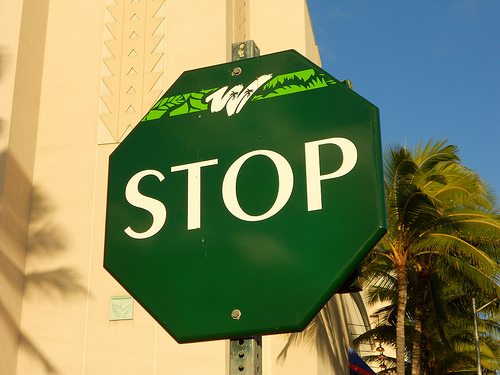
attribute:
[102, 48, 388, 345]
sign — octagon, green, large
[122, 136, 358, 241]
lettering — capitalized, white, stop, bold, large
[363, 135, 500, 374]
tree — green, branched, palm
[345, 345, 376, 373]
triangle — tiny, flag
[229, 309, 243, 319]
bolt — silver, small, tiny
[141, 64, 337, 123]
logo — white, green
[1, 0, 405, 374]
building — pink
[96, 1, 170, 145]
design — symmetrical, tan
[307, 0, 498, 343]
sky — blue, clear, overhead, crystal clear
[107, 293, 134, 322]
switch — small, white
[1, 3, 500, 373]
scene — tropical